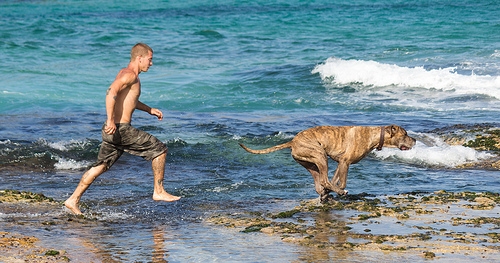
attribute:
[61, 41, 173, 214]
man — shirtless, running, walking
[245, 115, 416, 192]
dog — brindle, running, brown, big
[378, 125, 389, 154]
collar — brown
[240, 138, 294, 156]
tail — brown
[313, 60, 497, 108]
wave — white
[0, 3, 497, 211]
ocean — blue, large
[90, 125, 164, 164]
shorts — green, camo, grey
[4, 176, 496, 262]
shore — sand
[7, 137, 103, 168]
rocks — black